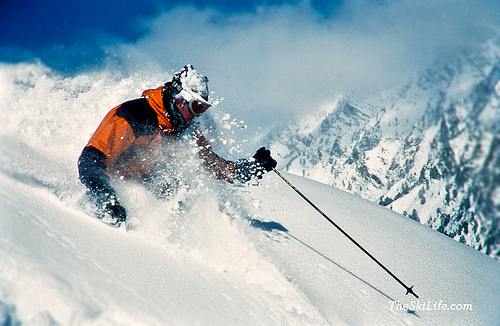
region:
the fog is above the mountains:
[128, 13, 498, 145]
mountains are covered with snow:
[281, 33, 496, 243]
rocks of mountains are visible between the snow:
[271, 43, 498, 234]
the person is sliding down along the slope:
[20, 69, 450, 321]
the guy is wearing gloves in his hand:
[76, 67, 273, 227]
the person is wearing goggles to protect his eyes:
[80, 65, 276, 226]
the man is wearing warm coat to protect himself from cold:
[75, 63, 273, 225]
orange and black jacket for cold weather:
[71, 85, 256, 219]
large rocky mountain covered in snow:
[220, 21, 499, 262]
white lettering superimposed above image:
[382, 295, 478, 317]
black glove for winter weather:
[245, 143, 280, 175]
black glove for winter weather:
[102, 200, 129, 225]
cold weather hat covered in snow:
[171, 59, 216, 100]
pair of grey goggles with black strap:
[167, 73, 215, 120]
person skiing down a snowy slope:
[73, 53, 300, 236]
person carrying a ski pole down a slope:
[66, 50, 423, 307]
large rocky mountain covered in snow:
[237, 5, 497, 270]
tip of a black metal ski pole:
[402, 282, 422, 303]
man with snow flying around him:
[66, 57, 281, 239]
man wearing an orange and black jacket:
[64, 54, 291, 244]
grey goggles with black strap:
[165, 76, 214, 119]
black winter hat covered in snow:
[167, 60, 214, 101]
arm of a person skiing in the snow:
[65, 90, 164, 231]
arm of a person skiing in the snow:
[182, 116, 277, 197]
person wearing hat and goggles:
[66, 60, 311, 254]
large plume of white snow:
[6, 53, 131, 198]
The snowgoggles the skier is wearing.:
[191, 99, 210, 120]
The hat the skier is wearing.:
[179, 67, 214, 96]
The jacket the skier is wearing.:
[79, 87, 232, 206]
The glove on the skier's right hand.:
[237, 147, 273, 177]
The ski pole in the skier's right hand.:
[270, 165, 433, 302]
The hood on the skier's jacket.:
[145, 84, 169, 132]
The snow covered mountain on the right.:
[262, 9, 498, 262]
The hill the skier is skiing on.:
[0, 146, 498, 321]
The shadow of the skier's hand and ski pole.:
[244, 214, 419, 319]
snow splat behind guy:
[31, 65, 58, 95]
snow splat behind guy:
[111, 59, 138, 94]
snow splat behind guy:
[74, 72, 96, 97]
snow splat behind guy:
[9, 66, 36, 106]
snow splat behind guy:
[67, 102, 93, 127]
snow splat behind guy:
[46, 159, 96, 189]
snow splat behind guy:
[10, 153, 52, 191]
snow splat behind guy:
[18, 123, 63, 142]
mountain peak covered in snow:
[241, 18, 496, 258]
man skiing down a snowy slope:
[66, 59, 290, 245]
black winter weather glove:
[99, 200, 132, 225]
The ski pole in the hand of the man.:
[266, 162, 421, 299]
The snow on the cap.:
[171, 63, 208, 102]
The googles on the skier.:
[171, 80, 213, 115]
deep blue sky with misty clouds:
[1, 1, 499, 86]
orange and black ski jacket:
[76, 84, 236, 191]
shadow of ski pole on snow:
[282, 227, 420, 317]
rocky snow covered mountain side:
[251, 33, 498, 255]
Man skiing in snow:
[80, 60, 276, 223]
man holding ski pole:
[76, 63, 420, 303]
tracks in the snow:
[0, 179, 142, 288]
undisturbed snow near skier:
[277, 170, 499, 324]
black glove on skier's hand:
[91, 195, 128, 223]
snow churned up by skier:
[3, 66, 206, 218]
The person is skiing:
[35, 44, 384, 299]